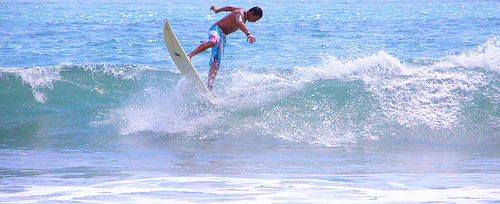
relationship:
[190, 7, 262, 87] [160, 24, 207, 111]
man on top of surfboard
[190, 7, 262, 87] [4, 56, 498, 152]
man surfing waves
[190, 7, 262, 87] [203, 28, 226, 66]
man wearing shorts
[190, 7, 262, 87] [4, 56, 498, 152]
man looking at waves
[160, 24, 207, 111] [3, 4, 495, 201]
surfboard in ocean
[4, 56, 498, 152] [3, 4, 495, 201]
waves in ocean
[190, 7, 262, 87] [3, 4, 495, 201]
man surfing in ocean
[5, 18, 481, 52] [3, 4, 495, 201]
ripples in ocean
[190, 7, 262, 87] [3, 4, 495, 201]
man in ocean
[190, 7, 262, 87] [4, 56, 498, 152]
man over waves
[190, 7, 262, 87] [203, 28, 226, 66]
man has shorts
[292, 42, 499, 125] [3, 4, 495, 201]
foam over ocean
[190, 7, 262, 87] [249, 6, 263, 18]
man has hair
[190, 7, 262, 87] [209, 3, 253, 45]
man has arms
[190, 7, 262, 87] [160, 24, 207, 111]
man riding surfboard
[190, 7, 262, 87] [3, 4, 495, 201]
man on top of ocean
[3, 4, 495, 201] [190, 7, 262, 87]
ocean with man